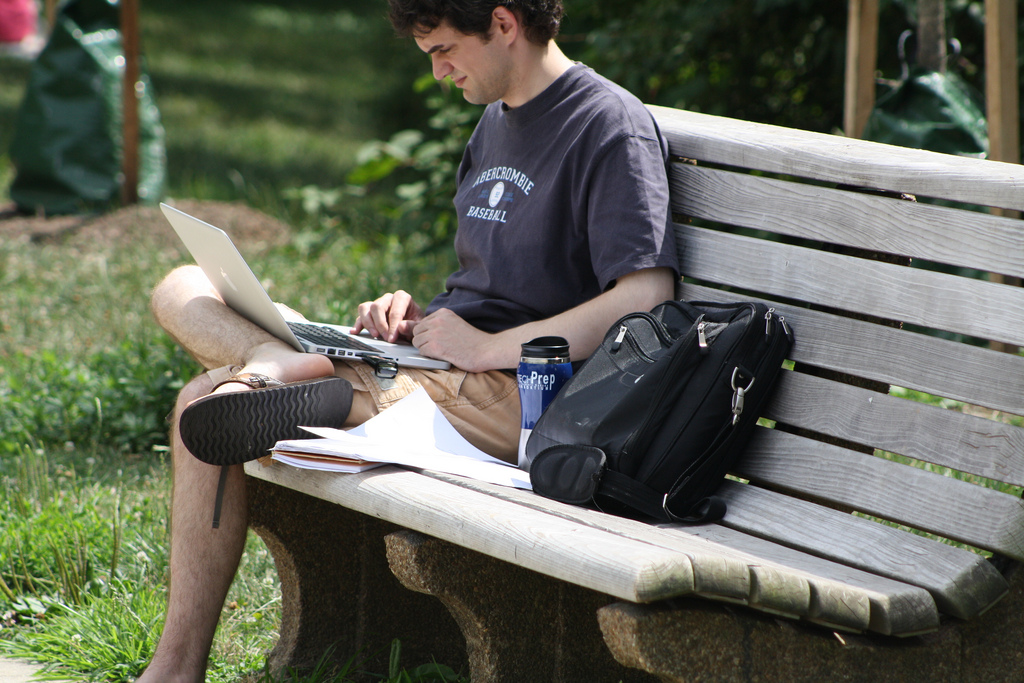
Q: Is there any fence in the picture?
A: No, there are no fences.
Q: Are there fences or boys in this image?
A: No, there are no fences or boys.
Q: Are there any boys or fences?
A: No, there are no fences or boys.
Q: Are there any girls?
A: No, there are no girls.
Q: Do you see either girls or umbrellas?
A: No, there are no girls or umbrellas.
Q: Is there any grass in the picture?
A: Yes, there is grass.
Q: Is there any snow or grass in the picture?
A: Yes, there is grass.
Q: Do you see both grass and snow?
A: No, there is grass but no snow.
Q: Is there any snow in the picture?
A: No, there is no snow.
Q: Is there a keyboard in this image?
A: Yes, there is a keyboard.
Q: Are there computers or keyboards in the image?
A: Yes, there is a keyboard.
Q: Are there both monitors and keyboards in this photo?
A: No, there is a keyboard but no monitors.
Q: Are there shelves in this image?
A: No, there are no shelves.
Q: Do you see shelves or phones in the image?
A: No, there are no shelves or phones.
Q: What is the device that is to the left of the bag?
A: The device is a keyboard.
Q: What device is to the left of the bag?
A: The device is a keyboard.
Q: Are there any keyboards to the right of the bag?
A: No, the keyboard is to the left of the bag.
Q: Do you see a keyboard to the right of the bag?
A: No, the keyboard is to the left of the bag.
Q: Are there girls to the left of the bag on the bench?
A: No, there is a keyboard to the left of the bag.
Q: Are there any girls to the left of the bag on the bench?
A: No, there is a keyboard to the left of the bag.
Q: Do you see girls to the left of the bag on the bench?
A: No, there is a keyboard to the left of the bag.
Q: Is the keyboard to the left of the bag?
A: Yes, the keyboard is to the left of the bag.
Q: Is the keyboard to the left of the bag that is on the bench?
A: Yes, the keyboard is to the left of the bag.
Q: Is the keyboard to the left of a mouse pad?
A: No, the keyboard is to the left of the bag.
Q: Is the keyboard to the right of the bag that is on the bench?
A: No, the keyboard is to the left of the bag.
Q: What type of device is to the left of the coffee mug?
A: The device is a keyboard.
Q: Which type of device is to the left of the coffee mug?
A: The device is a keyboard.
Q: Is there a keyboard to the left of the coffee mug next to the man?
A: Yes, there is a keyboard to the left of the coffee mug.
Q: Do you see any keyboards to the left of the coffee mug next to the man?
A: Yes, there is a keyboard to the left of the coffee mug.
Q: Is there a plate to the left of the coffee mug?
A: No, there is a keyboard to the left of the coffee mug.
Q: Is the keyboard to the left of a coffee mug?
A: Yes, the keyboard is to the left of a coffee mug.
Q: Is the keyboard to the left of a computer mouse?
A: No, the keyboard is to the left of a coffee mug.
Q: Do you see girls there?
A: No, there are no girls.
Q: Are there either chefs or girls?
A: No, there are no girls or chefs.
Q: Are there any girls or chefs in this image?
A: No, there are no girls or chefs.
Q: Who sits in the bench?
A: The man sits in the bench.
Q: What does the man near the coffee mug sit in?
A: The man sits in the bench.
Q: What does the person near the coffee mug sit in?
A: The man sits in the bench.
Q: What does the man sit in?
A: The man sits in the bench.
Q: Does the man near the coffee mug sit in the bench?
A: Yes, the man sits in the bench.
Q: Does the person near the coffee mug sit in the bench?
A: Yes, the man sits in the bench.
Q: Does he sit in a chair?
A: No, the man sits in the bench.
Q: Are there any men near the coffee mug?
A: Yes, there is a man near the coffee mug.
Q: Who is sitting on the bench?
A: The man is sitting on the bench.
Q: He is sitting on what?
A: The man is sitting on the bench.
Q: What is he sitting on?
A: The man is sitting on the bench.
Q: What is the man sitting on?
A: The man is sitting on the bench.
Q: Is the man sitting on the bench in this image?
A: Yes, the man is sitting on the bench.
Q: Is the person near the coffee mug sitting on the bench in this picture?
A: Yes, the man is sitting on the bench.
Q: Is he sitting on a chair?
A: No, the man is sitting on the bench.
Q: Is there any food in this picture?
A: No, there is no food.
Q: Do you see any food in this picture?
A: No, there is no food.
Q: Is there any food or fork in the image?
A: No, there are no food or forks.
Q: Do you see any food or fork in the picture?
A: No, there are no food or forks.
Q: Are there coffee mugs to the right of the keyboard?
A: Yes, there is a coffee mug to the right of the keyboard.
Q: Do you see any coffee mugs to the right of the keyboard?
A: Yes, there is a coffee mug to the right of the keyboard.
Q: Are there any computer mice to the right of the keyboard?
A: No, there is a coffee mug to the right of the keyboard.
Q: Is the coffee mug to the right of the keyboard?
A: Yes, the coffee mug is to the right of the keyboard.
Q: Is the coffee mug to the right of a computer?
A: No, the coffee mug is to the right of the keyboard.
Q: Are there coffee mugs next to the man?
A: Yes, there is a coffee mug next to the man.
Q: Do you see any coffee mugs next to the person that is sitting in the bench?
A: Yes, there is a coffee mug next to the man.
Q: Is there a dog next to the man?
A: No, there is a coffee mug next to the man.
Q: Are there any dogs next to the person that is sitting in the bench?
A: No, there is a coffee mug next to the man.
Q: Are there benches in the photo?
A: Yes, there is a bench.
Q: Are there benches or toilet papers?
A: Yes, there is a bench.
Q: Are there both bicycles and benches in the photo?
A: No, there is a bench but no bicycles.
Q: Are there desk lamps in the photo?
A: No, there are no desk lamps.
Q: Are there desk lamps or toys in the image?
A: No, there are no desk lamps or toys.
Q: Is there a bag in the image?
A: Yes, there is a bag.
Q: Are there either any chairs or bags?
A: Yes, there is a bag.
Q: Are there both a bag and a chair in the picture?
A: No, there is a bag but no chairs.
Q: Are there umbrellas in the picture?
A: No, there are no umbrellas.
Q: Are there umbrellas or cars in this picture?
A: No, there are no umbrellas or cars.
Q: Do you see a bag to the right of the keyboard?
A: Yes, there is a bag to the right of the keyboard.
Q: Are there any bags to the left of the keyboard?
A: No, the bag is to the right of the keyboard.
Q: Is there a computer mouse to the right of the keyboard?
A: No, there is a bag to the right of the keyboard.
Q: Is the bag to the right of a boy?
A: No, the bag is to the right of the keyboard.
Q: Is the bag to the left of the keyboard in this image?
A: No, the bag is to the right of the keyboard.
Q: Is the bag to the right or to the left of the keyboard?
A: The bag is to the right of the keyboard.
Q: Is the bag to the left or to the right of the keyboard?
A: The bag is to the right of the keyboard.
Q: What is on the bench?
A: The bag is on the bench.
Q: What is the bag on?
A: The bag is on the bench.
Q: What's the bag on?
A: The bag is on the bench.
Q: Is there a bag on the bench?
A: Yes, there is a bag on the bench.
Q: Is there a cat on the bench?
A: No, there is a bag on the bench.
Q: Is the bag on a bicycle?
A: No, the bag is on a bench.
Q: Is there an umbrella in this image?
A: No, there are no umbrellas.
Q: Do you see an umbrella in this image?
A: No, there are no umbrellas.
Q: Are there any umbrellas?
A: No, there are no umbrellas.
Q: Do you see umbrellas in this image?
A: No, there are no umbrellas.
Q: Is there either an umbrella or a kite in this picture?
A: No, there are no umbrellas or kites.